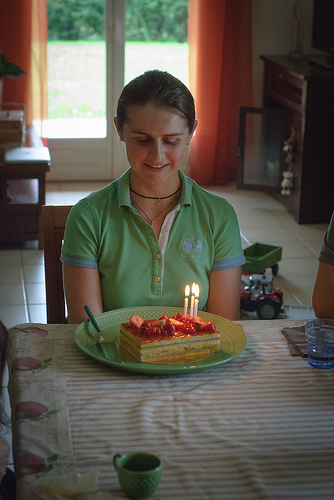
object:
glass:
[308, 325, 333, 362]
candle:
[184, 298, 189, 320]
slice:
[119, 308, 221, 350]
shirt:
[58, 167, 246, 315]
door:
[235, 107, 292, 192]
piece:
[241, 212, 286, 228]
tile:
[241, 226, 302, 243]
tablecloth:
[4, 316, 333, 500]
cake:
[115, 309, 226, 361]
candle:
[194, 297, 199, 321]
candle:
[190, 295, 195, 320]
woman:
[57, 68, 247, 323]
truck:
[241, 266, 286, 320]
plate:
[72, 305, 250, 375]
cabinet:
[236, 55, 334, 224]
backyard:
[44, 0, 190, 136]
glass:
[48, 0, 91, 58]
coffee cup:
[112, 451, 163, 500]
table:
[5, 314, 334, 499]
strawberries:
[129, 312, 144, 329]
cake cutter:
[83, 304, 120, 364]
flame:
[184, 284, 192, 296]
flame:
[194, 283, 200, 296]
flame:
[191, 281, 196, 295]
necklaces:
[127, 193, 182, 226]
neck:
[129, 168, 181, 210]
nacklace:
[130, 187, 182, 205]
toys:
[241, 271, 285, 319]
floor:
[0, 177, 333, 323]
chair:
[42, 205, 74, 324]